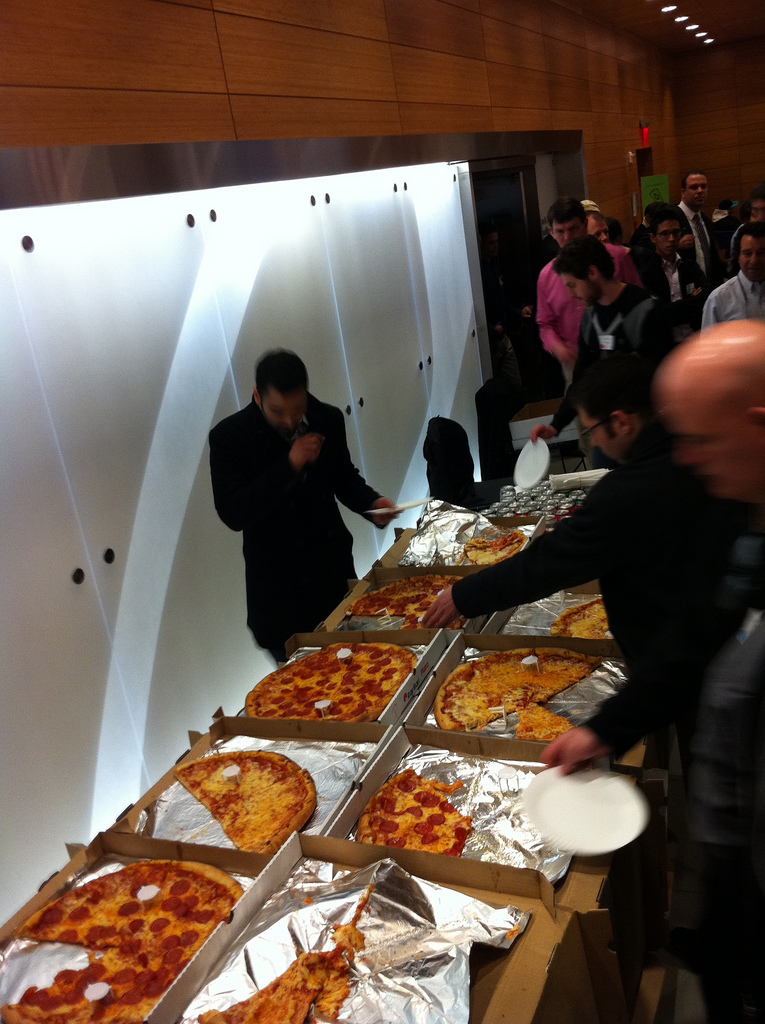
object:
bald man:
[540, 317, 765, 1023]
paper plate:
[523, 765, 650, 857]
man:
[207, 348, 400, 669]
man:
[535, 197, 644, 470]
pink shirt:
[535, 244, 643, 357]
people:
[700, 221, 765, 332]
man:
[420, 354, 722, 677]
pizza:
[344, 574, 468, 630]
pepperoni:
[413, 821, 434, 836]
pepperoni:
[427, 813, 446, 826]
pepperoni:
[397, 779, 416, 793]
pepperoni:
[356, 683, 374, 694]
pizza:
[0, 859, 243, 1024]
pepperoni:
[169, 879, 191, 896]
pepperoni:
[315, 679, 330, 687]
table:
[0, 469, 651, 1023]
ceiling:
[588, 5, 763, 41]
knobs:
[102, 548, 115, 565]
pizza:
[354, 767, 472, 858]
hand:
[539, 726, 601, 775]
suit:
[206, 392, 384, 667]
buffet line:
[4, 469, 645, 1022]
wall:
[0, 151, 492, 929]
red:
[641, 128, 648, 150]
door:
[458, 151, 591, 379]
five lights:
[660, 6, 714, 44]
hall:
[668, 963, 764, 1022]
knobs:
[71, 567, 85, 584]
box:
[103, 715, 392, 854]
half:
[173, 750, 317, 855]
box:
[0, 831, 274, 1024]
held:
[584, 710, 606, 738]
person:
[531, 233, 677, 469]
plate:
[514, 436, 551, 490]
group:
[481, 479, 587, 532]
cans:
[498, 507, 512, 517]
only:
[198, 879, 375, 1024]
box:
[141, 829, 572, 1024]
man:
[673, 172, 724, 288]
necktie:
[692, 213, 711, 279]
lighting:
[0, 160, 461, 243]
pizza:
[245, 641, 418, 723]